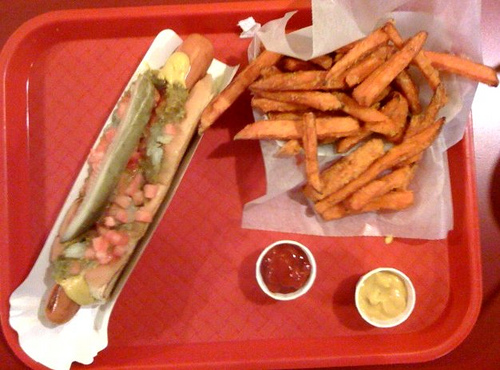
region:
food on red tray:
[7, 13, 492, 356]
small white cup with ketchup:
[245, 226, 315, 306]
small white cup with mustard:
[346, 255, 411, 331]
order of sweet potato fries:
[210, 17, 457, 222]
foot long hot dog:
[17, 21, 232, 316]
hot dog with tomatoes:
[17, 22, 207, 334]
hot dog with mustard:
[30, 30, 226, 330]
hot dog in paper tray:
[10, 20, 225, 341]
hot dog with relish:
[5, 30, 205, 360]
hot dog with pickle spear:
[25, 15, 210, 340]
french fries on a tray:
[218, 16, 454, 242]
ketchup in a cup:
[246, 228, 316, 318]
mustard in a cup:
[350, 262, 416, 333]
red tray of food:
[171, 242, 246, 355]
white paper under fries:
[425, 171, 451, 246]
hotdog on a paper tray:
[43, 36, 229, 362]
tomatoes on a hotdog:
[91, 227, 126, 262]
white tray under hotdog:
[6, 326, 101, 363]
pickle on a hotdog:
[45, 73, 158, 249]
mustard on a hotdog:
[156, 54, 196, 89]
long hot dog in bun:
[54, 64, 193, 290]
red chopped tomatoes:
[75, 83, 172, 288]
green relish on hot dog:
[75, 58, 196, 260]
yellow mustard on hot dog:
[55, 31, 219, 322]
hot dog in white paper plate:
[31, 35, 218, 346]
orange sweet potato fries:
[274, 32, 429, 213]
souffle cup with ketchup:
[263, 239, 303, 295]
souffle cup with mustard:
[354, 255, 411, 331]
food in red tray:
[15, 12, 468, 356]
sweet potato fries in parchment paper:
[242, 31, 458, 227]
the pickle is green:
[135, 90, 145, 124]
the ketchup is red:
[273, 260, 290, 275]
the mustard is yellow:
[373, 290, 390, 307]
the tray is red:
[178, 300, 211, 334]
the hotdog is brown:
[51, 297, 67, 312]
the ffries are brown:
[354, 63, 390, 91]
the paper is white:
[422, 174, 439, 209]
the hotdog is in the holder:
[50, 309, 80, 330]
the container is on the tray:
[246, 255, 263, 284]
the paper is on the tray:
[250, 167, 272, 202]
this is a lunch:
[24, 9, 466, 326]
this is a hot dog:
[54, 58, 232, 337]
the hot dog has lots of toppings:
[61, 38, 212, 321]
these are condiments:
[211, 240, 416, 352]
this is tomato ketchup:
[255, 245, 327, 301]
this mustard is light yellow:
[355, 266, 431, 321]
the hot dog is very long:
[32, 57, 238, 339]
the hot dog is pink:
[30, 281, 118, 366]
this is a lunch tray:
[135, 241, 237, 358]